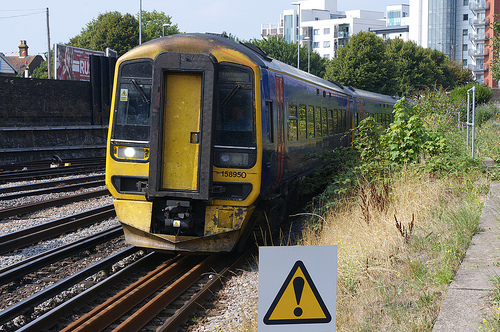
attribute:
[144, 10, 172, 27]
leaves — green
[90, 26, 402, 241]
cars — yellow, blue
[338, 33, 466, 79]
leaves — green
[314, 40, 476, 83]
leaves — green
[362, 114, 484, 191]
leaves — green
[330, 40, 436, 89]
leaves — green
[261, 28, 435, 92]
leaves — green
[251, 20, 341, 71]
leaves — green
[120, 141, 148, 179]
light — on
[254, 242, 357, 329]
sign — white, yellow danger sign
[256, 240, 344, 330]
sign — yellow danger sign, white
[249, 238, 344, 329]
sign — white, yellow danger sign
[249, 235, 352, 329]
sign — yellow danger sign, white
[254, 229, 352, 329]
sign — yellow danger sign, white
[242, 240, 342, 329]
sign — white, yellow danger sign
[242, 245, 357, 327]
sign — white, yellow danger sign